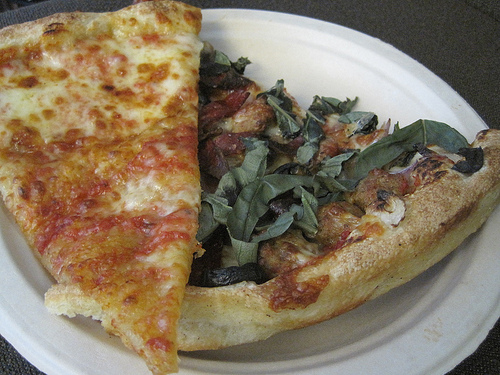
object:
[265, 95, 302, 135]
bacon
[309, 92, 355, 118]
bacon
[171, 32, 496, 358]
slice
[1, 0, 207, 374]
slice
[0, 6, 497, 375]
plate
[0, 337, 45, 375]
flat edge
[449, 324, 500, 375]
flat edge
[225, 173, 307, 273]
greens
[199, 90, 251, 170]
meat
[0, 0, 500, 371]
pizza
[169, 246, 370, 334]
crust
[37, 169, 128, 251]
sauce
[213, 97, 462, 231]
herbs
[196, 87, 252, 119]
red bacon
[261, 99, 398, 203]
toppings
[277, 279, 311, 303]
spot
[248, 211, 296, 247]
leaf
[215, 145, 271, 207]
leaf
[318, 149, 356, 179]
leaf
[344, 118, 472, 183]
leaf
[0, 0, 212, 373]
cheese